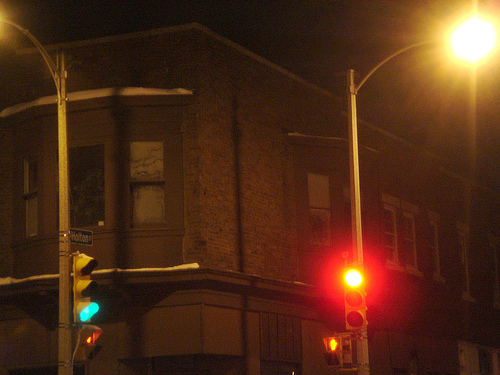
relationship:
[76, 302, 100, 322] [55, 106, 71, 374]
green light on pole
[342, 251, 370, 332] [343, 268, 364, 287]
signal with a right light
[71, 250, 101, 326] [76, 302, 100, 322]
signal with a green light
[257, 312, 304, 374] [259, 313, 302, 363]
small window that has a blocks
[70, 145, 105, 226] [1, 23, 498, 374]
black window on building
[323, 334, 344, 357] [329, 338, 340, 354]
smaller signal with a light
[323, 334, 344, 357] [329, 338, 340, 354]
smaller signal with a red light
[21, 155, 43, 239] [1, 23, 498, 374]
window on side of building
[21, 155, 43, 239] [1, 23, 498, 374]
window on building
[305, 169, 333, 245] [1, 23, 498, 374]
window on side of building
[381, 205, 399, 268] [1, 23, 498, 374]
window on building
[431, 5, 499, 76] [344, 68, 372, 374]
lamp on a pole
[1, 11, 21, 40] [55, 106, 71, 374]
lamp on a pole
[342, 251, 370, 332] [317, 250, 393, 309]
traffic signal with blaring light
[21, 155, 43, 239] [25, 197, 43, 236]
window with section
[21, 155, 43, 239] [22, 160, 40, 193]
window with section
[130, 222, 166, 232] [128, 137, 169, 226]
ledge of a window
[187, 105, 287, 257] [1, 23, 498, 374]
bricks on side of a building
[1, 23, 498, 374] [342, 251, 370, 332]
brown brick building behind signal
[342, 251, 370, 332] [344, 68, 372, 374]
signal attached to a pole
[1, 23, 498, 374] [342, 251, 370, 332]
brick building near signal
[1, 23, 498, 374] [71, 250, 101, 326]
brick building near signal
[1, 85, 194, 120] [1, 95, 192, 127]
snow on ledge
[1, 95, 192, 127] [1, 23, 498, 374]
ledge of building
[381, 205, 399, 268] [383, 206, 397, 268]
window with white frame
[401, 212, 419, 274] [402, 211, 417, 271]
window with white frame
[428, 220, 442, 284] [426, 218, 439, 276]
window with white frame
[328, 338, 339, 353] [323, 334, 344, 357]
orange light on crossing sign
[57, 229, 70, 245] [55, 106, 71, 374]
metal ring around pole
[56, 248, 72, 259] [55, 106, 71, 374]
metal ring around pole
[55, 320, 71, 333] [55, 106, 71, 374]
metal ring around pole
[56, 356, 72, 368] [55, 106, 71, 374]
metal ring around pole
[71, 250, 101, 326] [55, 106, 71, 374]
traffic signal on pole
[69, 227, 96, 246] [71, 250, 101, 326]
green sign above traffic signal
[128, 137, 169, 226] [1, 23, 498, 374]
window on building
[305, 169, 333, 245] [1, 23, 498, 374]
window on building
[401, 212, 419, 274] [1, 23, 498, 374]
window on building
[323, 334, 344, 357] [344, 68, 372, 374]
street walking light on pole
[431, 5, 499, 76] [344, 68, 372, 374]
street light on pole